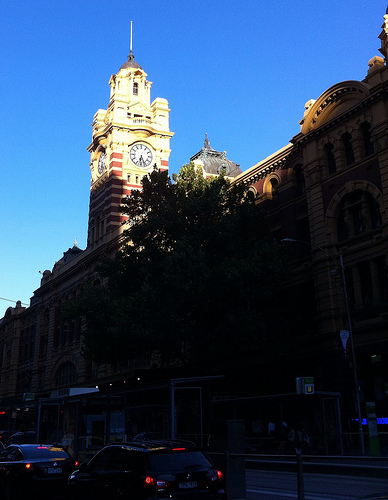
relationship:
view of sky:
[1, 4, 380, 307] [179, 12, 333, 76]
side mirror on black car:
[70, 457, 80, 466] [0, 440, 82, 491]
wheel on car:
[68, 486, 85, 499] [70, 439, 227, 498]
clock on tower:
[126, 139, 156, 170] [86, 20, 175, 245]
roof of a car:
[109, 434, 176, 455] [64, 433, 231, 498]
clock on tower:
[87, 148, 113, 180] [90, 11, 172, 251]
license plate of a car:
[178, 480, 198, 488] [64, 433, 231, 498]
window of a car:
[94, 448, 142, 472] [70, 439, 227, 498]